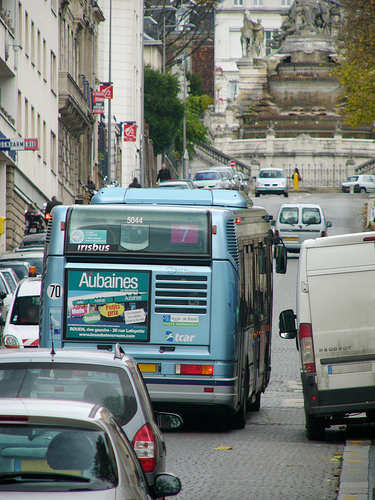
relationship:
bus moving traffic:
[40, 179, 277, 409] [0, 160, 358, 494]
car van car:
[284, 230, 373, 437] [284, 230, 373, 437]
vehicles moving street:
[0, 160, 358, 494] [80, 177, 361, 486]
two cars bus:
[0, 349, 168, 498] [40, 179, 277, 409]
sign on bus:
[64, 266, 158, 343] [40, 179, 277, 409]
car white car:
[284, 230, 373, 437] [287, 241, 374, 406]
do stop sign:
[227, 158, 238, 170] [64, 266, 158, 343]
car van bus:
[284, 230, 373, 437] [40, 179, 277, 409]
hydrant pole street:
[291, 167, 300, 190] [80, 177, 361, 486]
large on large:
[239, 8, 271, 67] [239, 8, 271, 67]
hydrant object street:
[291, 167, 300, 190] [80, 177, 361, 486]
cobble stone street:
[199, 435, 294, 498] [80, 177, 361, 486]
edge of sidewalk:
[323, 441, 362, 498] [327, 441, 372, 499]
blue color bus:
[149, 270, 236, 364] [40, 179, 277, 409]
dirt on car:
[303, 331, 365, 398] [284, 230, 373, 437]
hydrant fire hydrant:
[291, 167, 300, 190] [283, 173, 304, 194]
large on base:
[239, 8, 271, 67] [232, 61, 269, 104]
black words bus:
[61, 294, 148, 341] [40, 179, 277, 409]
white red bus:
[43, 283, 64, 300] [40, 179, 277, 409]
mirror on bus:
[270, 246, 292, 273] [40, 179, 277, 409]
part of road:
[204, 424, 308, 487] [80, 177, 361, 486]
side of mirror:
[268, 242, 290, 274] [270, 246, 292, 273]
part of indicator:
[195, 360, 215, 382] [173, 358, 223, 382]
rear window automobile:
[3, 422, 113, 470] [0, 396, 153, 498]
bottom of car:
[303, 402, 369, 419] [287, 241, 374, 406]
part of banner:
[6, 135, 45, 160] [0, 136, 48, 155]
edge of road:
[323, 441, 362, 498] [80, 177, 361, 486]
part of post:
[100, 8, 125, 192] [96, 2, 124, 188]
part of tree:
[143, 77, 180, 140] [138, 64, 190, 149]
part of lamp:
[106, 123, 116, 159] [108, 6, 120, 205]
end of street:
[242, 176, 347, 204] [80, 177, 361, 486]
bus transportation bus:
[40, 179, 290, 429] [40, 179, 277, 409]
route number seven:
[166, 223, 205, 247] [174, 226, 194, 244]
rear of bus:
[3, 422, 113, 470] [40, 179, 277, 409]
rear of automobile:
[3, 422, 113, 470] [0, 352, 153, 490]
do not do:
[227, 158, 238, 170] [227, 158, 238, 170]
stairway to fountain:
[188, 99, 265, 168] [217, 105, 342, 144]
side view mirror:
[268, 242, 290, 274] [270, 246, 292, 273]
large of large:
[239, 8, 271, 67] [239, 8, 271, 67]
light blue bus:
[50, 198, 243, 358] [40, 179, 277, 409]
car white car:
[284, 230, 373, 437] [284, 230, 373, 437]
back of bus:
[52, 203, 227, 349] [40, 179, 277, 409]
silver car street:
[6, 402, 125, 498] [80, 177, 361, 486]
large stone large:
[224, 0, 274, 84] [239, 8, 271, 67]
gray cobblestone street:
[171, 430, 292, 492] [80, 177, 361, 486]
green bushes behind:
[152, 81, 194, 130] [142, 65, 202, 127]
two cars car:
[0, 349, 168, 498] [284, 230, 373, 437]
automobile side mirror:
[0, 396, 153, 498] [270, 246, 292, 273]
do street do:
[227, 158, 238, 170] [227, 158, 238, 170]